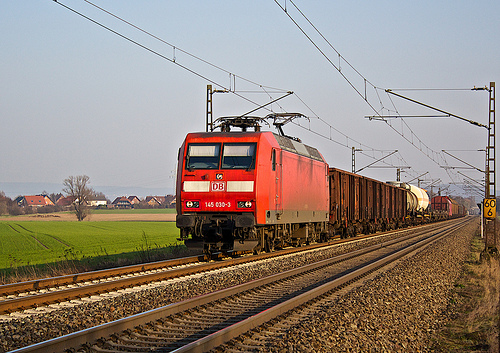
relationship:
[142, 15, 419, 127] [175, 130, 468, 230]
lines on train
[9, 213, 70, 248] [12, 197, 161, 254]
track on field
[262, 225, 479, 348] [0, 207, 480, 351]
pebbles of train tracks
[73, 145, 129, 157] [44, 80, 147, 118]
clouds in sky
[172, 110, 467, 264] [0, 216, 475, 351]
train on rails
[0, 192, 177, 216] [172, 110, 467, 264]
homes near train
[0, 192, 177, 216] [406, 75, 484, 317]
homes near station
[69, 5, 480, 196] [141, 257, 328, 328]
wires over railroad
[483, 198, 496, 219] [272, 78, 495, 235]
sign over electrical pole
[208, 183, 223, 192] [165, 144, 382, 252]
letters on a train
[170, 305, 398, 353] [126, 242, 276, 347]
gravel on a track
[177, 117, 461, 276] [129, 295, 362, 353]
train moving down track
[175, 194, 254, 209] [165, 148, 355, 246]
headlights on front of train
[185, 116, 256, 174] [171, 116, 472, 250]
windows on front of train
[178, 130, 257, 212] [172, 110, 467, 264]
train front belonging to train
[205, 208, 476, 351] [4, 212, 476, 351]
edge lining rail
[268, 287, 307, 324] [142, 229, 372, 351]
edge of a rail